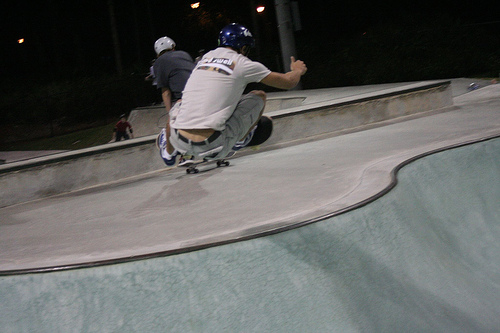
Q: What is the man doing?
A: Skateboarding.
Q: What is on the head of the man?
A: Helmet.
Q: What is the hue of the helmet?
A: Dark blue.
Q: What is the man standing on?
A: Skateboard.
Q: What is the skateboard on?
A: Concrete.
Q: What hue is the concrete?
A: Gray.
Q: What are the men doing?
A: Skateboarding.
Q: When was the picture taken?
A: After dark.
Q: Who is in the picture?
A: Two men.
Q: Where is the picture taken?
A: A skatepark.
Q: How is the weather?
A: Clear.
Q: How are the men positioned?
A: Crouching.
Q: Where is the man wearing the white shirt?
A: The foreground.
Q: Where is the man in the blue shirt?
A: The background.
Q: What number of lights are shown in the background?
A: Three.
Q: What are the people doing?
A: Skateboarding.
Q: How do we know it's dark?
A: Lights are on.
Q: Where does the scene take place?
A: Skatepark.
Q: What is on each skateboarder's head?
A: Helmet.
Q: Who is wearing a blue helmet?
A: Skateboarder.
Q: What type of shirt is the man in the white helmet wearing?
A: Tee shirt.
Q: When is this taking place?
A: Night time.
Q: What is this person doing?
A: Skateboarding.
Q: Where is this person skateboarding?
A: Skate ramp.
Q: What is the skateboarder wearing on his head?
A: Helmet.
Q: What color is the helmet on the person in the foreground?
A: Black.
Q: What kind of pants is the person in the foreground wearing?
A: Jeans.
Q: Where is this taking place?
A: Skatepark.